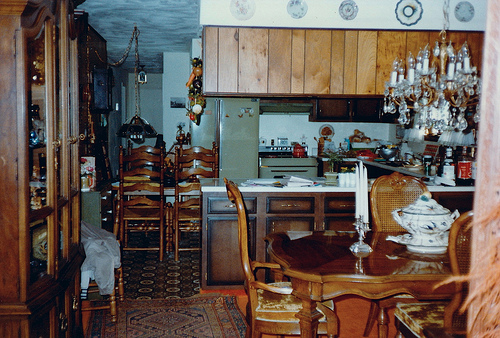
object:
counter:
[202, 184, 226, 193]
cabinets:
[324, 196, 356, 213]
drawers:
[266, 198, 356, 213]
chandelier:
[382, 29, 480, 131]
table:
[264, 233, 452, 277]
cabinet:
[0, 1, 85, 338]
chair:
[222, 177, 337, 338]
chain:
[441, 7, 450, 28]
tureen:
[400, 191, 451, 215]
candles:
[354, 161, 369, 240]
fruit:
[185, 59, 206, 125]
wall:
[76, 0, 500, 90]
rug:
[107, 294, 244, 338]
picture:
[170, 96, 185, 108]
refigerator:
[219, 98, 260, 179]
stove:
[268, 157, 317, 172]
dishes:
[234, 0, 474, 26]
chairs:
[114, 141, 219, 262]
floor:
[121, 250, 201, 299]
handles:
[282, 204, 298, 207]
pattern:
[170, 280, 176, 292]